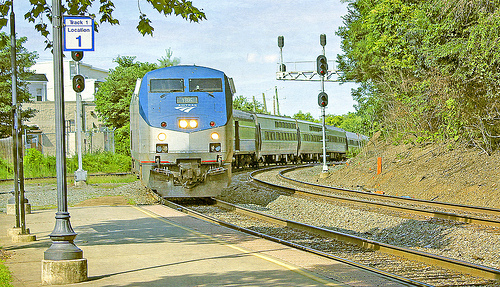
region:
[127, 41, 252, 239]
the locomotive is blue & silver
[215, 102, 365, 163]
the rest of the cars appear green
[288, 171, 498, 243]
another set of tracks run parelell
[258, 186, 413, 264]
gravel is in between the tracks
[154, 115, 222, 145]
the headlights are on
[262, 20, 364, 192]
railroad signals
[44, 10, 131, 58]
the sign is blue & white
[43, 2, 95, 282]
light poles line the area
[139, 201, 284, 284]
a yellow line runs along the curb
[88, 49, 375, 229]
this is a long train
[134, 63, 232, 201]
the front of the train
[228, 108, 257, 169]
a car of the train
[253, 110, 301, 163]
a car of the train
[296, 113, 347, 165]
a cr of the train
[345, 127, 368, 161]
a car of the train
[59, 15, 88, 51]
a blue and white sign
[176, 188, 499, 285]
train tracks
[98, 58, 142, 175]
a tree with green leaves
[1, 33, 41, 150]
a tree with green leaves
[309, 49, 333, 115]
an unlit traffic signal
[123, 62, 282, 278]
a train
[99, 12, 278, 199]
a train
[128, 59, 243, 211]
front of train on tracks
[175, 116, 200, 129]
lights on front of train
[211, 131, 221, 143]
lights on front of train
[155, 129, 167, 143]
lights on front of train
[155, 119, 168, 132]
lights on front of train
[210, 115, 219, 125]
lights on front of train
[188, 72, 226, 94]
window on front of train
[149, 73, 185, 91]
window on front of train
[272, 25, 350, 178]
stop light on side of track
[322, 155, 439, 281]
railroad tracks on side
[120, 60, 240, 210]
Front of a passenger train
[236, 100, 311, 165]
Passenger cars of a train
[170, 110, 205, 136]
Lights of a passenger train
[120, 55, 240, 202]
Locomotive pulling a passenger train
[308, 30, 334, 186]
Lights at a railroad crossing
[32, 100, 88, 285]
Pole at a railroad crossing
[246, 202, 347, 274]
Railroad tracks at a railroad crossing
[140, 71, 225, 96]
Front windows of a locomotive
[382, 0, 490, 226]
Bushes beside a railroad crossing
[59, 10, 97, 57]
Sign at a railroad crossing